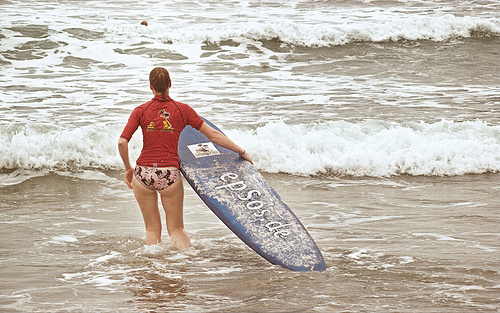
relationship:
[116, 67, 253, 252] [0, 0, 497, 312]
woman at ocean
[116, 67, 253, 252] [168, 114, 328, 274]
woman with surfboard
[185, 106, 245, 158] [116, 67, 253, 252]
arm of woman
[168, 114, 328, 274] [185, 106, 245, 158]
surfboard under arm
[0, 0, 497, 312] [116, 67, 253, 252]
ocean before woman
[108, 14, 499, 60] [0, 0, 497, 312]
wave in ocean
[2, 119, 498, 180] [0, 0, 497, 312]
foam of ocean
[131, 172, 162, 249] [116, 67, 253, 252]
leg of woman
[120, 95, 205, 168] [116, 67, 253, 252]
shirt on woman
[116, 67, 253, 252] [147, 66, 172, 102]
woman styled hair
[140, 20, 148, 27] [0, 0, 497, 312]
head in ocean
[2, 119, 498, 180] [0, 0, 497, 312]
foam in ocean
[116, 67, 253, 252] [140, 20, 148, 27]
woman watching head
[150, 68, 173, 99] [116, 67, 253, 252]
head of woman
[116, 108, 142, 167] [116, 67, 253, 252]
arm on woman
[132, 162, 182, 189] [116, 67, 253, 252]
suit of woman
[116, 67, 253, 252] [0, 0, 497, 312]
woman in ocean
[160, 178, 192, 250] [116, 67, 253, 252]
leg of woman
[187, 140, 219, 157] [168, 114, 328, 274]
logo on surfboard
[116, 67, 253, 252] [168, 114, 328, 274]
woman holding surfboard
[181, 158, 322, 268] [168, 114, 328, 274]
sand on surfboard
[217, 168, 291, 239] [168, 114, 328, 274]
letters on surfboard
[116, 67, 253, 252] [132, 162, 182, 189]
woman in suit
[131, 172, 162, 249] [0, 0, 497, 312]
leg in ocean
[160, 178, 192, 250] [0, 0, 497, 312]
leg in ocean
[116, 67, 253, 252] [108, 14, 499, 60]
woman watches wave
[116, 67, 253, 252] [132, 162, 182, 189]
woman has suit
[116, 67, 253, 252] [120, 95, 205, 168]
woman wearing shirt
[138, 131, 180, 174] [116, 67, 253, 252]
body of woman